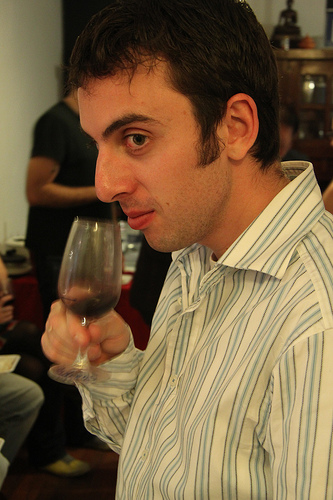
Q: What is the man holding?
A: Wine glass.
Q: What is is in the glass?
A: Wine.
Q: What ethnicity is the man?
A: White.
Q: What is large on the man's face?
A: Nose.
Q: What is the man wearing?
A: Striped Shirt.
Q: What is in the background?
A: A person.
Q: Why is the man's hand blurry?
A: Moving.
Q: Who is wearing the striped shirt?
A: A man.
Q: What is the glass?
A: Wine.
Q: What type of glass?
A: Long stem glass.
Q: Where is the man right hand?
A: Holding glass.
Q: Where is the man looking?
A: To left.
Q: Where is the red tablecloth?
A: On table.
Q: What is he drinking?
A: Wine.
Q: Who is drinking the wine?
A: The man.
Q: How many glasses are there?
A: One.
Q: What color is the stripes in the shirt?
A: Blue.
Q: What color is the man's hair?
A: Brown.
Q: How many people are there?
A: Three.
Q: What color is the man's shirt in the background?
A: Black.